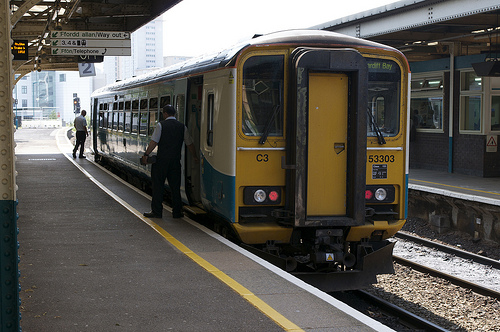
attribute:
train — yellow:
[232, 30, 406, 239]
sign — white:
[48, 24, 131, 55]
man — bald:
[149, 103, 187, 225]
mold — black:
[244, 182, 282, 206]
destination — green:
[363, 56, 398, 75]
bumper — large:
[290, 222, 392, 284]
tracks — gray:
[385, 300, 429, 329]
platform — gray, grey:
[65, 233, 110, 273]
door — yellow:
[308, 70, 353, 218]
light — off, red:
[266, 188, 283, 206]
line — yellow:
[179, 239, 217, 279]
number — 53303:
[367, 151, 404, 165]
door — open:
[188, 79, 205, 205]